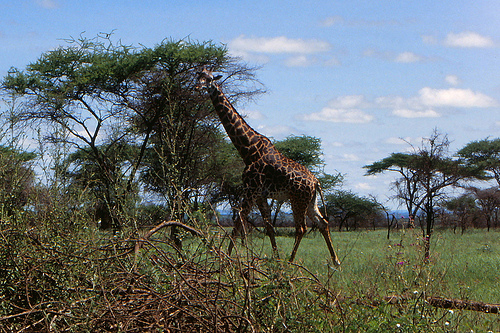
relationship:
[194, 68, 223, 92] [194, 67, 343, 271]
head of giraffe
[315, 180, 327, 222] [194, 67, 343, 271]
tail of giraffe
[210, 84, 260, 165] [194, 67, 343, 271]
neck of giraffe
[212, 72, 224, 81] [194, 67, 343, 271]
ear of giraffe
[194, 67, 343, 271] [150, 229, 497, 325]
giraffe on grass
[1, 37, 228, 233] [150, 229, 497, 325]
tree on grass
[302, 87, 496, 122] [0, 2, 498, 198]
clouds in sky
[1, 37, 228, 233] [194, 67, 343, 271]
tree near giraffe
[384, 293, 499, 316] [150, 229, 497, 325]
wood on grass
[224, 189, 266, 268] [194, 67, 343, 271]
leg of giraffe